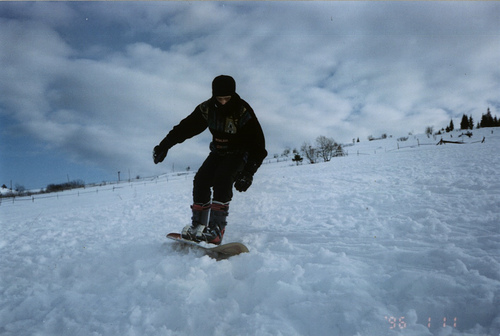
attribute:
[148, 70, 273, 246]
person — snowboarding, leaning, snowskating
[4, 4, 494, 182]
sky — blue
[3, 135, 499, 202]
fence — low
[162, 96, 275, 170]
jacket — black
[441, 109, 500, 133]
trees — far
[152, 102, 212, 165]
arm — raised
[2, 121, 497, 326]
snow — white, fluffy, rough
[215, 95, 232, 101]
eyes — exposed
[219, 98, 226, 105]
nose — exposed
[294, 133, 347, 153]
branches — bare